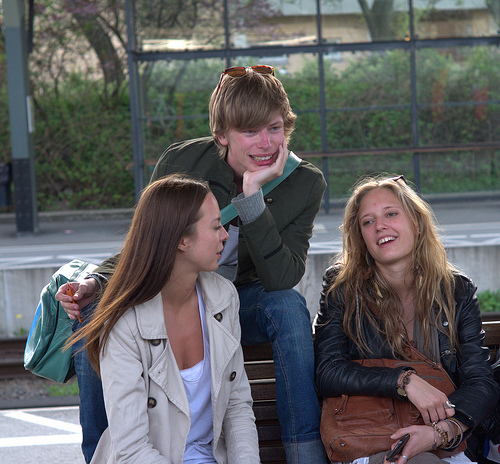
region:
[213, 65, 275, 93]
a pair of sunglasses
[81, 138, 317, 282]
a light green tight fit jacket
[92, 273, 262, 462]
a white pea-coat with dark buttons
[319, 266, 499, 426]
a black leather jacket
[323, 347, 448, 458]
a large brown leather bag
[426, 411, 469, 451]
row of worn bracelets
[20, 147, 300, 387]
a seafoam green shoulder bag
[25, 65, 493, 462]
a group of teens sitting on a bench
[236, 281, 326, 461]
left leg wearing bllue jeans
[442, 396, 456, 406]
a large ring with dark stone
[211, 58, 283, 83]
BROWN SUNGLASSES ON A MANS HEAD.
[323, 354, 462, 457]
A LARGE BROWN LEATHER PURSE.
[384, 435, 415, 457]
A SMALL BLACK CELL PHONE.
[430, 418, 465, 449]
SEVERAL BRACELETS ON A WOMANS WRIST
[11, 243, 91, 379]
A LIGHT GREEN OR TURQUOISE SATCHEL.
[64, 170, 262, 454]
A WOMAN IN A WHITE JACKET.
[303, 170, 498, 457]
A WOMAN IN A BLACK JACKET.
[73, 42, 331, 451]
A MAN IN JEANS AND A GREEN SWEATER.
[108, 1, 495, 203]
A LARGE FENCE BEHIND THE GROUP.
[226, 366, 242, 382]
A LARGE BROWN BUTTON.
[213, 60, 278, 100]
a pair of sunglasses on top of the boy's head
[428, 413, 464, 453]
a bunch of bracelet's on the girl's wrist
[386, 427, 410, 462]
a cell phone in the girl's left hand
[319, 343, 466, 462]
a large brown purse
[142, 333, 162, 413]
buttons on the girl's trench coat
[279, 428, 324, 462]
the bottom of the boy's jeans is rolled up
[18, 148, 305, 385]
a blue bag over the boy's shoulders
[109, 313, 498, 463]
a wooden park bench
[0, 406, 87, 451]
white lines painted on the street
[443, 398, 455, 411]
a silver ring on the girl's finger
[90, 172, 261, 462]
A woman in a tan jacket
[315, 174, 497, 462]
A girl in a leather coat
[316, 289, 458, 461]
A brown leather bag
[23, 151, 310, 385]
A blue messenger bag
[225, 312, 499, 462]
A outdoor wooden bench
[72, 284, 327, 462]
A pair of blue jeans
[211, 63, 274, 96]
A pair of sun glasses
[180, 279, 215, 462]
A light blue tank top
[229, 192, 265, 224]
A grey sweater cuff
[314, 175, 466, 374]
Curly blond hair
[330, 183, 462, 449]
girl on the bench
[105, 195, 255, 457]
girl on the bench